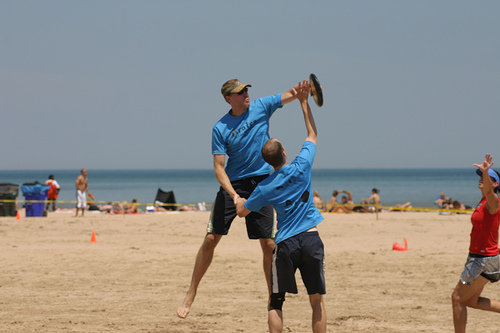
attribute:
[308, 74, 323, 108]
frisbee — black, gold, dark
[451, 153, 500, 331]
woman — reaching, reaching up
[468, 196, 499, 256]
shirt — red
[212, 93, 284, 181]
t shirt — blue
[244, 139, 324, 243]
t shirt — blue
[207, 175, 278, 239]
shorts — dark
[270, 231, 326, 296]
shorts — black, dark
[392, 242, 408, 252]
cone — orange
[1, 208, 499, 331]
beach — sand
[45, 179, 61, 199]
shirt — red, white, orange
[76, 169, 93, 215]
guy — shirtless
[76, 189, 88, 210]
pants — white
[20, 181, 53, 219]
recycle bin — blue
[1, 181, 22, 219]
trash bin — black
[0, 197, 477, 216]
crossing tape — yellow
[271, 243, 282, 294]
stripe — white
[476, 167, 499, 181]
visor — gray, blue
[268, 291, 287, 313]
knee brace — black